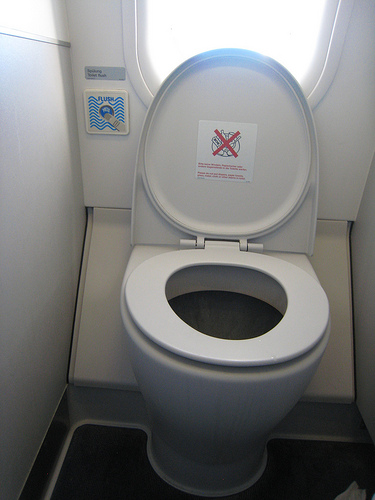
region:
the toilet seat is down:
[120, 243, 324, 363]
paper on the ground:
[330, 480, 365, 495]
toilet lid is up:
[132, 48, 316, 254]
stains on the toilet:
[210, 392, 253, 468]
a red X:
[210, 130, 239, 155]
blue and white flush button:
[83, 91, 129, 134]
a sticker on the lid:
[195, 120, 255, 182]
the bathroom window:
[145, 3, 328, 82]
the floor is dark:
[46, 424, 374, 498]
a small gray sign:
[84, 68, 124, 79]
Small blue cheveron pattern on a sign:
[87, 119, 127, 125]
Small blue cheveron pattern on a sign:
[86, 114, 128, 122]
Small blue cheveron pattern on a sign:
[87, 110, 125, 118]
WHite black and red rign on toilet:
[184, 117, 263, 198]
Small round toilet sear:
[119, 239, 315, 370]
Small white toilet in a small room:
[106, 223, 304, 486]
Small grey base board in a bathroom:
[56, 377, 349, 494]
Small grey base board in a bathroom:
[6, 381, 102, 499]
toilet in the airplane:
[123, 183, 318, 468]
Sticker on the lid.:
[192, 115, 258, 184]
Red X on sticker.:
[210, 122, 245, 160]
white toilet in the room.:
[118, 46, 343, 497]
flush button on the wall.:
[79, 88, 132, 139]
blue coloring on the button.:
[80, 85, 130, 140]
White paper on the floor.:
[330, 474, 371, 498]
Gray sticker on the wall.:
[79, 61, 129, 84]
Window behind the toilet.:
[124, 2, 351, 126]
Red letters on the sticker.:
[191, 157, 250, 182]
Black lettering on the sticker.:
[82, 63, 114, 81]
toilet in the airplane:
[115, 116, 331, 404]